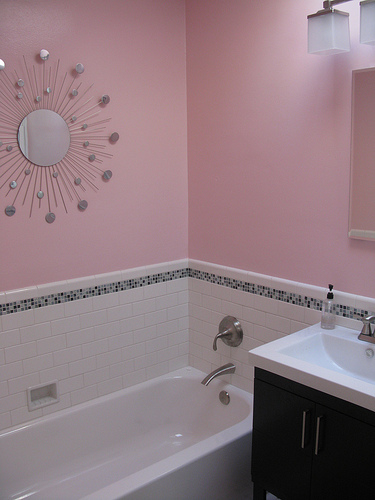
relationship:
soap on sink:
[319, 280, 339, 329] [256, 313, 374, 395]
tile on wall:
[163, 293, 173, 309] [4, 2, 375, 302]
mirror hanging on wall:
[20, 107, 71, 170] [2, 4, 192, 299]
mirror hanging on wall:
[343, 64, 375, 241] [188, 2, 374, 297]